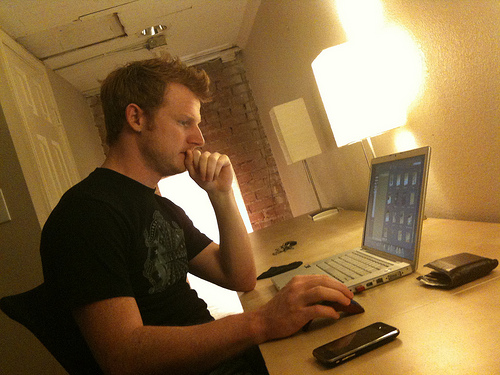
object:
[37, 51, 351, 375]
man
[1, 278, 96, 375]
chair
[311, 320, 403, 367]
cell phone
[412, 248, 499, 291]
wallet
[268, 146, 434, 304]
laptop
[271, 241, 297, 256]
keys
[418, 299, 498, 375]
table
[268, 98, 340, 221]
lamp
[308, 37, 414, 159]
lamp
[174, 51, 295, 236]
wall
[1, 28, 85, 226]
door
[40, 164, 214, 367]
shirt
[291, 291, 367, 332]
mouse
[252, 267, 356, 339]
hand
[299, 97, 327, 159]
shade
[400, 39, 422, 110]
shade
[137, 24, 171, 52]
light fixture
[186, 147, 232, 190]
hand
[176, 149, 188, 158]
mouth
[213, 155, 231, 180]
fingers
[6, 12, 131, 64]
tile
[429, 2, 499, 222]
wall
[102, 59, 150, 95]
hair